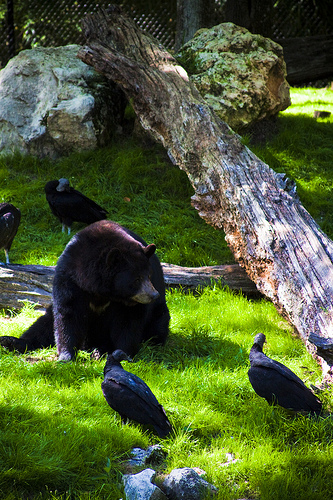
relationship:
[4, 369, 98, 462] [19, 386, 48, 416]
lawn with grass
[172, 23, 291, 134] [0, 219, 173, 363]
rock behind bear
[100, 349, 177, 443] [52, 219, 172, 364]
bird in front of bear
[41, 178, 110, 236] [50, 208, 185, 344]
bird behind bear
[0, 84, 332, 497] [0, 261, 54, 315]
grass on structure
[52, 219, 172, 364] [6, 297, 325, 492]
bear standing in grass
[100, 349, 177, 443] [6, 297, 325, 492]
bird standing in grass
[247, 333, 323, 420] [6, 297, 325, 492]
bird standing in grass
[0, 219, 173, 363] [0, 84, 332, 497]
bear standing in grass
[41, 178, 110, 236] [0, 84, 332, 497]
bird standing in grass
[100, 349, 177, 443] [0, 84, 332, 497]
bird standing in grass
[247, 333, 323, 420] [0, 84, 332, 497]
bird standing in grass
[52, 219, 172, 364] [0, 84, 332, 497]
bear standing in grass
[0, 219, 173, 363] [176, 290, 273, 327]
bear standing in grass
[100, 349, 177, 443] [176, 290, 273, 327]
bird standing in grass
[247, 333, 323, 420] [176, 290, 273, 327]
bird standing in grass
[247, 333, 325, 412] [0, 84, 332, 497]
bird standing in grass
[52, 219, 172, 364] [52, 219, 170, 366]
bear with hair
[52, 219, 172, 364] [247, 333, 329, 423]
bear sitting with bird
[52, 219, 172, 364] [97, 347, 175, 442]
bear sitting with bird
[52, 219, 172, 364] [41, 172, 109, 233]
bear sitting with bird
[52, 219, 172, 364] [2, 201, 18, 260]
bear sitting with bird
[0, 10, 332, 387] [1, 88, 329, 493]
tree laying on ground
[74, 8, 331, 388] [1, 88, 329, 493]
log on ground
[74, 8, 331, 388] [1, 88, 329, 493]
log laying on ground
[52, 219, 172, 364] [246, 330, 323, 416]
bear looking at bird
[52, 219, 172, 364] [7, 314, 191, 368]
bear on ground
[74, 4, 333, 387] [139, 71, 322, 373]
log from a tree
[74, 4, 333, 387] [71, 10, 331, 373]
log from a tree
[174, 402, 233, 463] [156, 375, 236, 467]
sunlight on grass